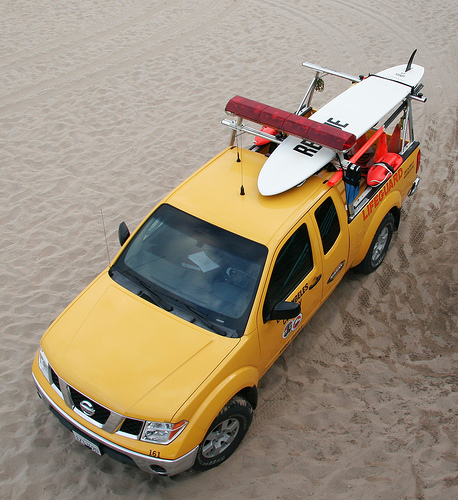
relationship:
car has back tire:
[29, 60, 427, 482] [351, 211, 395, 275]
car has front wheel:
[29, 60, 427, 482] [193, 393, 253, 474]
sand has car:
[1, 3, 455, 497] [29, 60, 427, 482]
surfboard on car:
[256, 42, 443, 235] [29, 60, 427, 482]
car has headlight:
[29, 60, 427, 482] [38, 353, 48, 379]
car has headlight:
[29, 60, 427, 482] [36, 348, 49, 382]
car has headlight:
[29, 60, 427, 482] [139, 418, 186, 446]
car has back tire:
[29, 60, 427, 482] [363, 206, 395, 272]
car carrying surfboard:
[29, 60, 427, 482] [250, 47, 424, 194]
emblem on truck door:
[280, 324, 293, 339] [267, 249, 325, 334]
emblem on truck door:
[294, 316, 302, 327] [267, 249, 325, 334]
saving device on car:
[368, 151, 402, 188] [29, 60, 427, 482]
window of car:
[317, 198, 337, 250] [29, 60, 427, 482]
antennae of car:
[93, 197, 118, 295] [29, 60, 427, 482]